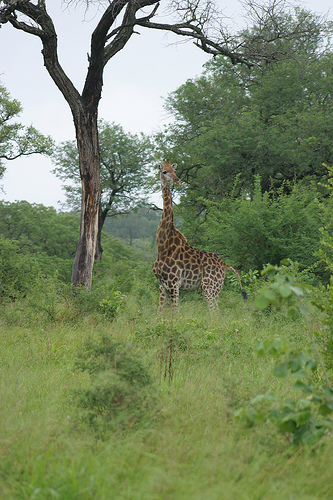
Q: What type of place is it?
A: It is a field.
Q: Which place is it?
A: It is a field.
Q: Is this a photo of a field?
A: Yes, it is showing a field.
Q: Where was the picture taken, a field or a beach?
A: It was taken at a field.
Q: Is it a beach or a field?
A: It is a field.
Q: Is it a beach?
A: No, it is a field.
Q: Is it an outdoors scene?
A: Yes, it is outdoors.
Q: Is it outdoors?
A: Yes, it is outdoors.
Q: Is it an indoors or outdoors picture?
A: It is outdoors.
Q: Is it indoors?
A: No, it is outdoors.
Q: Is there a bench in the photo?
A: No, there are no benches.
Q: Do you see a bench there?
A: No, there are no benches.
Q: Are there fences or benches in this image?
A: No, there are no benches or fences.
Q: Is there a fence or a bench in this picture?
A: No, there are no benches or fences.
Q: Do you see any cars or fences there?
A: No, there are no cars or fences.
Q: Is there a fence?
A: No, there are no fences.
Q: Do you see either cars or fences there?
A: No, there are no fences or cars.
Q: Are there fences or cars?
A: No, there are no fences or cars.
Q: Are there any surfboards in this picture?
A: No, there are no surfboards.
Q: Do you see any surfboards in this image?
A: No, there are no surfboards.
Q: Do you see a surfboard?
A: No, there are no surfboards.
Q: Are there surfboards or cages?
A: No, there are no surfboards or cages.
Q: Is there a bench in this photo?
A: No, there are no benches.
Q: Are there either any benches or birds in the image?
A: No, there are no benches or birds.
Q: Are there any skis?
A: No, there are no skis.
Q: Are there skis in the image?
A: No, there are no skis.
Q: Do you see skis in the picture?
A: No, there are no skis.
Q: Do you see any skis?
A: No, there are no skis.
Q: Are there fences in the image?
A: No, there are no fences.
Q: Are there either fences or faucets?
A: No, there are no fences or faucets.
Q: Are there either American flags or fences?
A: No, there are no fences or American flags.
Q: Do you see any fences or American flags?
A: No, there are no fences or American flags.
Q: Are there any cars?
A: No, there are no cars.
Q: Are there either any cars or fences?
A: No, there are no cars or fences.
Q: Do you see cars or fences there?
A: No, there are no cars or fences.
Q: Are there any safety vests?
A: No, there are no safety vests.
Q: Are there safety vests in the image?
A: No, there are no safety vests.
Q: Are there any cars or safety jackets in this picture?
A: No, there are no safety jackets or cars.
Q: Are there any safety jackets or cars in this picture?
A: No, there are no safety jackets or cars.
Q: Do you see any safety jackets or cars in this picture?
A: No, there are no safety jackets or cars.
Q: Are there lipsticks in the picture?
A: No, there are no lipsticks.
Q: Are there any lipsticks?
A: No, there are no lipsticks.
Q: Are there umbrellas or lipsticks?
A: No, there are no lipsticks or umbrellas.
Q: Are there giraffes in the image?
A: Yes, there is a giraffe.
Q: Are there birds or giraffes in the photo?
A: Yes, there is a giraffe.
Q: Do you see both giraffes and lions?
A: No, there is a giraffe but no lions.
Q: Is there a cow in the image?
A: No, there are no cows.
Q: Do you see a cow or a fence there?
A: No, there are no cows or fences.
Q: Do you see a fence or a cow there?
A: No, there are no cows or fences.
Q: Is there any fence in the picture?
A: No, there are no fences.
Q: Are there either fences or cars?
A: No, there are no fences or cars.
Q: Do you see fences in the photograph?
A: No, there are no fences.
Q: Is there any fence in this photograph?
A: No, there are no fences.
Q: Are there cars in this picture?
A: No, there are no cars.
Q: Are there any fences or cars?
A: No, there are no cars or fences.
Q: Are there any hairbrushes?
A: No, there are no hairbrushes.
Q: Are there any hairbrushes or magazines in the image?
A: No, there are no hairbrushes or magazines.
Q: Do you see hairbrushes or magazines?
A: No, there are no hairbrushes or magazines.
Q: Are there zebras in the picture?
A: No, there are no zebras.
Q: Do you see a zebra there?
A: No, there are no zebras.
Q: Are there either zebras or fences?
A: No, there are no zebras or fences.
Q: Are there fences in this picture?
A: No, there are no fences.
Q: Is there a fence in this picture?
A: No, there are no fences.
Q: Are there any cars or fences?
A: No, there are no fences or cars.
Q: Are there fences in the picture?
A: No, there are no fences.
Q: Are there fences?
A: No, there are no fences.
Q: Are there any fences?
A: No, there are no fences.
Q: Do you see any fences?
A: No, there are no fences.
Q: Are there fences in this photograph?
A: No, there are no fences.